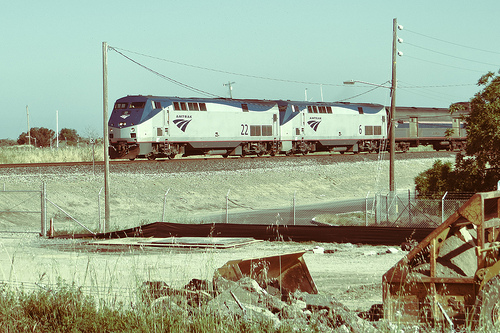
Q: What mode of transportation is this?
A: Train.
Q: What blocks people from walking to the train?
A: Fence.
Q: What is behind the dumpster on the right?
A: Trees.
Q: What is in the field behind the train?
A: Trees.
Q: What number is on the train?
A: 22.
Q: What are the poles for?
A: Electricity.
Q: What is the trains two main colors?
A: White and blue.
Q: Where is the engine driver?
A: Front of train.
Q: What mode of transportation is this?
A: Train.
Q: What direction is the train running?
A: To the left.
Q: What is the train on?
A: Rail.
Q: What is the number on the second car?
A: 6.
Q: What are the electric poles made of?
A: Wood.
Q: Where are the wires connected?
A: To poles.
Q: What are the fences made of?
A: Metal.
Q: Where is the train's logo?
A: On the side of the engine.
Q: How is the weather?
A: Clear.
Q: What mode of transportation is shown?
A: Train.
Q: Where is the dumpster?
A: A dirt road.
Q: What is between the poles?
A: Wires.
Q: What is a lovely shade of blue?
A: The sky.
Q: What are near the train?
A: Trees.